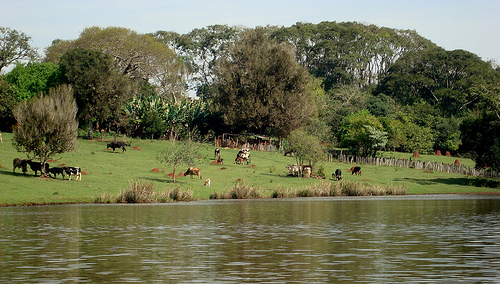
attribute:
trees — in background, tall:
[31, 25, 472, 152]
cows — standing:
[11, 156, 97, 182]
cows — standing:
[287, 163, 356, 183]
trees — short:
[286, 132, 332, 167]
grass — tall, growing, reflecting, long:
[122, 181, 400, 202]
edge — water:
[22, 192, 417, 204]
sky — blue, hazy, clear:
[11, 4, 491, 27]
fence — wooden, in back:
[341, 154, 468, 178]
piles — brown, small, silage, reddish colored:
[151, 167, 186, 180]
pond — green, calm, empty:
[12, 209, 494, 276]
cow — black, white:
[66, 162, 83, 181]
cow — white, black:
[236, 149, 252, 165]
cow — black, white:
[302, 163, 315, 179]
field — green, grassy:
[6, 132, 482, 196]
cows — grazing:
[283, 161, 384, 186]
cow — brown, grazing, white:
[186, 165, 207, 181]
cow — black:
[28, 156, 48, 178]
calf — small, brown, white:
[202, 178, 215, 190]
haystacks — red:
[132, 142, 186, 182]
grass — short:
[85, 154, 142, 185]